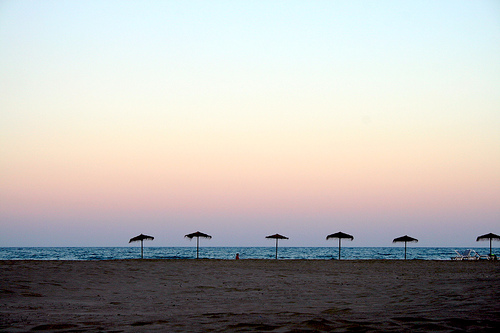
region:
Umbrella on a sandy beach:
[123, 225, 496, 272]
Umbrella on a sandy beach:
[126, 225, 160, 267]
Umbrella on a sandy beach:
[181, 226, 214, 261]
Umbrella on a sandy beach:
[262, 230, 292, 260]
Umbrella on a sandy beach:
[326, 223, 352, 264]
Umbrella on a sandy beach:
[392, 228, 424, 263]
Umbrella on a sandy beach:
[475, 220, 499, 272]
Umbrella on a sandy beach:
[324, 225, 422, 269]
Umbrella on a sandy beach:
[184, 225, 296, 262]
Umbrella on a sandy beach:
[130, 218, 215, 257]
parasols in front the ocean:
[116, 225, 493, 256]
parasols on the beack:
[5, 226, 495, 331]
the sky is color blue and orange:
[0, 0, 494, 222]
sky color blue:
[6, 6, 483, 83]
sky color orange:
[7, 126, 497, 209]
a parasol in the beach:
[125, 223, 157, 267]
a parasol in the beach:
[179, 223, 215, 262]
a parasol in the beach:
[261, 227, 290, 257]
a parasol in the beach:
[323, 223, 357, 265]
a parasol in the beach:
[386, 229, 420, 263]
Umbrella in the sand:
[128, 228, 158, 263]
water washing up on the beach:
[22, 245, 132, 275]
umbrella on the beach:
[184, 227, 211, 274]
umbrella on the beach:
[264, 230, 288, 260]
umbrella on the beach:
[323, 226, 355, 263]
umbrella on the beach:
[391, 228, 421, 264]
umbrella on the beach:
[474, 225, 498, 266]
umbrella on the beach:
[128, 227, 156, 264]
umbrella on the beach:
[181, 221, 228, 275]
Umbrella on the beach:
[123, 228, 154, 260]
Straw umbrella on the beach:
[179, 223, 215, 260]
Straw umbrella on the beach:
[258, 221, 293, 260]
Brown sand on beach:
[0, 257, 495, 330]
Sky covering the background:
[0, 10, 498, 244]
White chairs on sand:
[445, 246, 495, 263]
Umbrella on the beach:
[324, 230, 359, 261]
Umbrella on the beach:
[388, 223, 423, 261]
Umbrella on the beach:
[470, 225, 499, 260]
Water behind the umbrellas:
[1, 243, 498, 268]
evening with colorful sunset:
[0, 8, 499, 242]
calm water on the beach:
[0, 242, 495, 263]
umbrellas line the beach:
[124, 227, 497, 259]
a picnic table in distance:
[446, 246, 478, 261]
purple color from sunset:
[3, 199, 272, 233]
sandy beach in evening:
[1, 262, 498, 330]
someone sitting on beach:
[228, 247, 239, 258]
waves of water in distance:
[31, 249, 56, 258]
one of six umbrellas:
[387, 232, 419, 257]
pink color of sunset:
[6, 164, 74, 199]